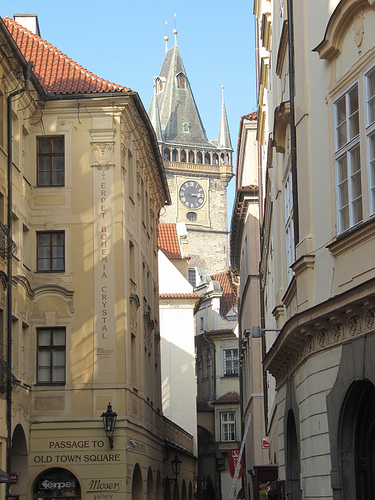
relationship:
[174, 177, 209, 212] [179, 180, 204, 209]
clock has face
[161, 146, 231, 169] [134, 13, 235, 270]
archways on clock tower